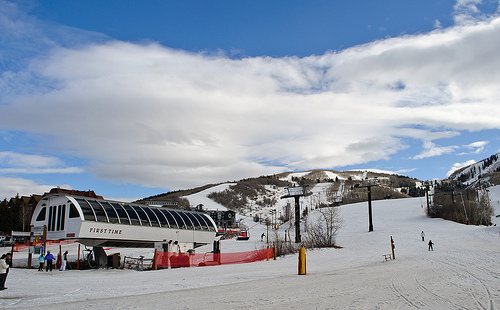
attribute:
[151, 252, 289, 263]
fence — mesh fence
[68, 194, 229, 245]
roof — buildings,  building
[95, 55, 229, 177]
cloud — white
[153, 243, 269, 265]
fence — red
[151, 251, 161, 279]
pole — black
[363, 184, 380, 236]
pole — large